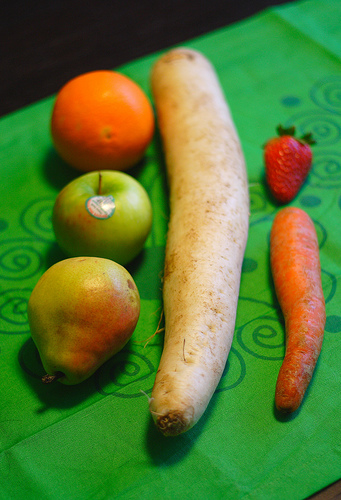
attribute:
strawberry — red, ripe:
[260, 122, 317, 201]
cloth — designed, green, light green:
[1, 2, 339, 499]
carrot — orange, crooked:
[265, 206, 325, 417]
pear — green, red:
[26, 256, 140, 387]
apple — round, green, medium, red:
[50, 168, 152, 268]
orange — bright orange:
[50, 71, 154, 172]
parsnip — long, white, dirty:
[148, 47, 249, 437]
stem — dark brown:
[40, 366, 68, 387]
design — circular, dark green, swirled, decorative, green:
[0, 73, 340, 399]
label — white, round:
[85, 192, 116, 221]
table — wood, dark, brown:
[1, 0, 340, 500]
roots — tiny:
[144, 391, 197, 441]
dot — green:
[280, 94, 303, 109]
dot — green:
[298, 189, 323, 210]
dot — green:
[322, 310, 340, 340]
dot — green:
[239, 253, 261, 277]